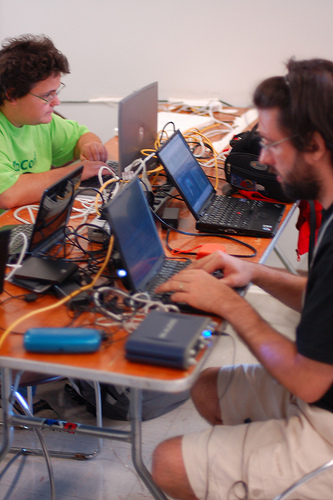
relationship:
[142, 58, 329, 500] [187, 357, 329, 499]
man wearing shorts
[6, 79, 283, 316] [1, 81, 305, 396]
laptops on table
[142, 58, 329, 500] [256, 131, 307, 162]
man wearing glasses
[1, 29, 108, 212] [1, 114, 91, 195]
man wearing shirt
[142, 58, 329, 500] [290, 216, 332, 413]
man wearing shirt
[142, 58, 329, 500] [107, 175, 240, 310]
man using laptop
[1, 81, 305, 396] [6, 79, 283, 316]
table has laptops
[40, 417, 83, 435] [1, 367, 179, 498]
sticker on leg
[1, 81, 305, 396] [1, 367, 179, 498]
table has leg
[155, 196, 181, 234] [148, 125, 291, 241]
power adapter for laptop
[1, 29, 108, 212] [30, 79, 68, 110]
man wearing glasses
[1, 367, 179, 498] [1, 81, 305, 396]
leg under table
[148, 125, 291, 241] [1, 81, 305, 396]
laptop on table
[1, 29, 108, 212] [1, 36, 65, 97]
man has hair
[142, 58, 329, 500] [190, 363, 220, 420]
man has knee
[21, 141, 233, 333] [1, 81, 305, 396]
computer cables on table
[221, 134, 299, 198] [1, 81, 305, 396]
modem on table